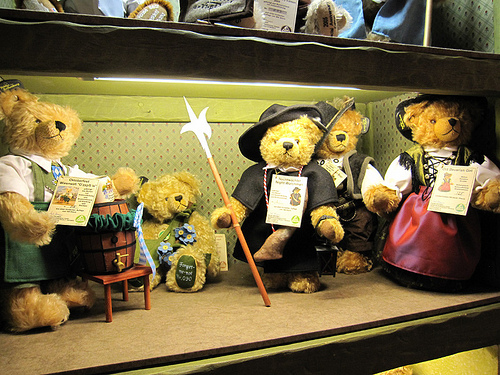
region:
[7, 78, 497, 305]
several bears on a shelf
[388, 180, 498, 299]
red skirt on bear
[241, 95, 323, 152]
black hat on bear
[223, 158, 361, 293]
black jacket on bear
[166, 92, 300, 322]
a bear holding a pole with sharp end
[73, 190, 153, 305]
a barrel sits on a table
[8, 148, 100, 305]
a green jumper on bear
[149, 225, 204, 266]
blue flowers on a bear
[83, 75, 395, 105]
a light above the bears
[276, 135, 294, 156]
black nose of a bear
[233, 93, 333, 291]
This is a ted bear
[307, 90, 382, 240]
This is a ted bear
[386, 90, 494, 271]
This is a ted bear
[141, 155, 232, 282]
This is a ted bear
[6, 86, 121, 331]
This is a ted bear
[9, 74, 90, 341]
This is a tedbear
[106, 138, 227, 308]
This is a tedbear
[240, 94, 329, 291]
This is a tedbear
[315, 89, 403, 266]
This is a tedbear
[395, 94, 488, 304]
This is a tedbear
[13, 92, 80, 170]
Head of a tedbear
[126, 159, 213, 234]
Head of a tedbear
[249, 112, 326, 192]
Head of a tedbear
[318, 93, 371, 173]
Head of a tedbear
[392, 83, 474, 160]
Head of a tedbear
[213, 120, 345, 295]
a brown teddy bear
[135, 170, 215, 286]
a brown teddy bear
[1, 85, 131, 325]
a brown teddy bear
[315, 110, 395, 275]
a brown teddy bear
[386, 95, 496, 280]
a brown teddy bear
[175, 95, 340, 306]
a teddy bear holding a staff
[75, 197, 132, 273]
a toy barrel keg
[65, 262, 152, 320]
a small toy table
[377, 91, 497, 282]
a bear in traditional german costume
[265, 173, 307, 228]
a toy informational card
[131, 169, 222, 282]
A teddy bear in the photo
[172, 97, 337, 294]
A teddy bear with a stroke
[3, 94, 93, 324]
A teddy with a piece of paper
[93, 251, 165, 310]
A wooden stool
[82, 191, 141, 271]
A barrel on the stool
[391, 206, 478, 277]
A pink dress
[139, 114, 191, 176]
A wall in the background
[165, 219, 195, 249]
A floral tie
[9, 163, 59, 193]
Green and white shirt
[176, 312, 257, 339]
A wooden table